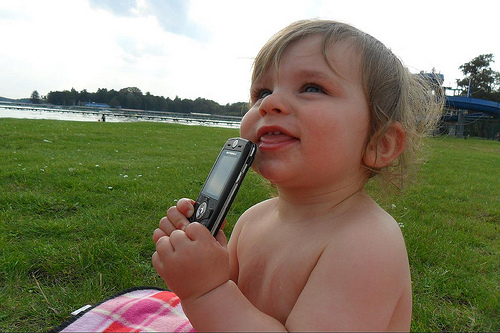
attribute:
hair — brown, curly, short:
[244, 12, 440, 80]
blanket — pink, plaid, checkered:
[35, 276, 187, 329]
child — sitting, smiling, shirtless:
[123, 8, 419, 332]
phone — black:
[167, 111, 272, 260]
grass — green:
[8, 135, 146, 279]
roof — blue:
[86, 101, 109, 111]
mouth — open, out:
[253, 119, 302, 154]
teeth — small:
[267, 123, 294, 139]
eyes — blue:
[227, 51, 348, 95]